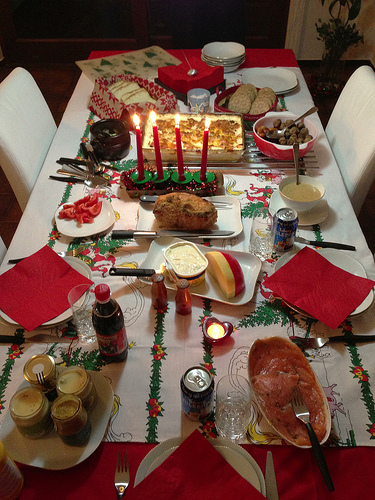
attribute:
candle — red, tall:
[131, 115, 149, 184]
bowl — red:
[251, 110, 318, 161]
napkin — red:
[2, 245, 99, 325]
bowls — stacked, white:
[199, 38, 246, 74]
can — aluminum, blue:
[180, 365, 214, 425]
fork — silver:
[111, 451, 136, 500]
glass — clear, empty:
[215, 372, 254, 444]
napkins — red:
[156, 53, 226, 93]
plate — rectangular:
[133, 234, 265, 307]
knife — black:
[109, 227, 236, 243]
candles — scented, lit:
[129, 110, 215, 184]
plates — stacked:
[240, 67, 300, 99]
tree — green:
[233, 294, 300, 332]